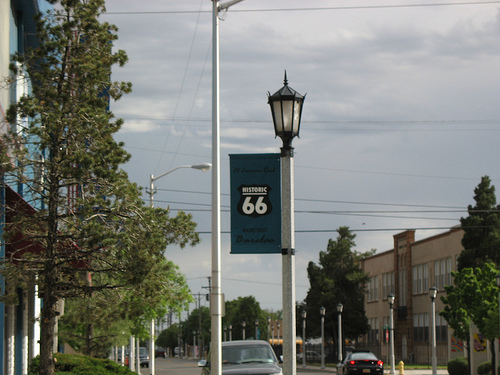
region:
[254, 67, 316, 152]
A street light on top of a pole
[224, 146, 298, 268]
A blue, black and white sign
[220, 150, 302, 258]
Historice 66 sign on a pole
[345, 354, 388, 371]
Red brake lights on a car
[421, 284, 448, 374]
A street lamp on the street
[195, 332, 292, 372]
A car parked behind a pole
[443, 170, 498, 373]
A Green tree in front of a building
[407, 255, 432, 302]
Three windows on the second floor of a building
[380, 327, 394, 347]
A stop sign on the street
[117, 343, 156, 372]
A car parked down the street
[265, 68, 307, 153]
Black lamps with white glass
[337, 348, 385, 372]
Back end of a black car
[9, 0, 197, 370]
Green tree in the foreground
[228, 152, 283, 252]
Historic Route 66 sign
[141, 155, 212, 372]
White streetlight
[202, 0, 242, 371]
Tall white pole for a power line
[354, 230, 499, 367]
Two story tan building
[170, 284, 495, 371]
Line of lampposts down the street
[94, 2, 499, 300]
Cloudy, gray sky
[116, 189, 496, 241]
Four power lines crossing the street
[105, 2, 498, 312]
cloud cover in sky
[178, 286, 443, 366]
row of lights on poles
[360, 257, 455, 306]
row of windows on building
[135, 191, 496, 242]
black wires suspended in mid air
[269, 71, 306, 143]
light with black trim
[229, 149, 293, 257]
vertical sign on pole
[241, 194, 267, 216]
white numbers on black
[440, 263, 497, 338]
green leaves on tree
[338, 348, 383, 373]
glowing red lights on car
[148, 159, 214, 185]
light on horizontal pole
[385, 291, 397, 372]
a tall street light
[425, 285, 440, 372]
a tall street light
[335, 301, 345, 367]
a tall street light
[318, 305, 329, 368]
a tall street light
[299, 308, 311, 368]
a tall street light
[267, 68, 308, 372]
a tall street light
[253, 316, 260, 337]
a tall street light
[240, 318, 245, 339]
a tall street light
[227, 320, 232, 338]
a tall street light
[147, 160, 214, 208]
a tall street light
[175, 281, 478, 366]
row of street lights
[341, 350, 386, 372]
car with glowing red lights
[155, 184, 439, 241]
suspended black wires over street